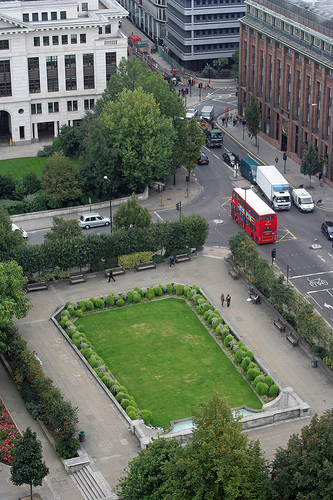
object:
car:
[76, 211, 111, 230]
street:
[11, 14, 333, 330]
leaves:
[207, 441, 219, 461]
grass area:
[71, 291, 268, 431]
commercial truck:
[255, 165, 292, 212]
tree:
[7, 422, 50, 499]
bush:
[267, 382, 280, 398]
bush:
[174, 281, 185, 298]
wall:
[236, 400, 310, 433]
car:
[320, 219, 333, 243]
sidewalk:
[9, 162, 201, 234]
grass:
[73, 294, 266, 426]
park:
[0, 247, 333, 499]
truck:
[254, 163, 290, 211]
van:
[290, 187, 315, 214]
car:
[197, 151, 210, 167]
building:
[0, 1, 129, 145]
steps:
[84, 463, 109, 496]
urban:
[0, 0, 333, 498]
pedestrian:
[107, 269, 116, 282]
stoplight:
[199, 160, 203, 162]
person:
[225, 293, 231, 308]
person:
[220, 292, 225, 306]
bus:
[229, 187, 278, 245]